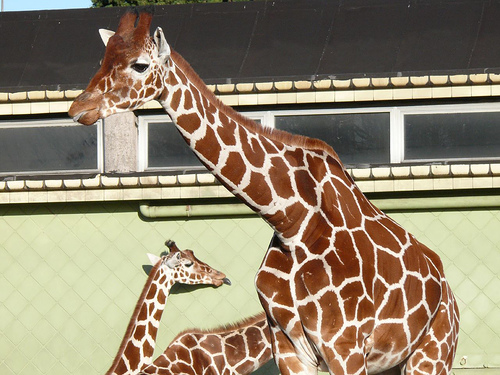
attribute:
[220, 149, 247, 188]
spot — brown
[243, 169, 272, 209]
spot — brown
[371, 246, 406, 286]
spot — brown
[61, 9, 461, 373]
giraffe — large, brown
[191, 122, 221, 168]
spot — brown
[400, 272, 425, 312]
spot — brown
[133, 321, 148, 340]
spot — brown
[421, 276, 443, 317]
spot — brown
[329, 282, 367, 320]
spot — brown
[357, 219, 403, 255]
spot — brown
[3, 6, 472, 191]
roof — black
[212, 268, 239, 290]
tongue — out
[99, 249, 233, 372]
giraffe — small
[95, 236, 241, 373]
giraffe — tall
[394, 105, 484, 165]
window — large, square, rectangular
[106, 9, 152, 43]
horns — short, brown, furry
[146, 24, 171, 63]
ear — small, white, furry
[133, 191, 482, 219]
pipe — long, green, metal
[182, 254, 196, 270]
eye — round, almond, black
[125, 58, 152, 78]
eye — dark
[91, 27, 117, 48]
ear — white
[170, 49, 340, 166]
mane — short, brown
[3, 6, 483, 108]
roof — black